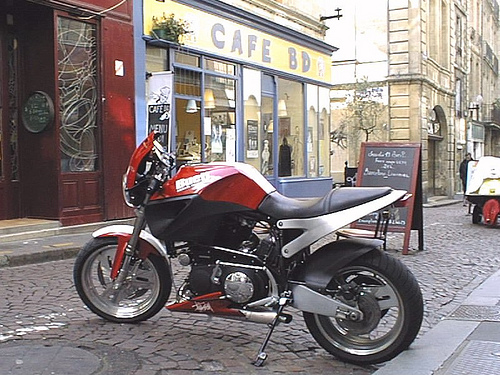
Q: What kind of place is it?
A: It is a road.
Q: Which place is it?
A: It is a road.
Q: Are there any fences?
A: No, there are no fences.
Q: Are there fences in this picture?
A: No, there are no fences.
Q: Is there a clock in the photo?
A: No, there are no clocks.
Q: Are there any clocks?
A: No, there are no clocks.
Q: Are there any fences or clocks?
A: No, there are no clocks or fences.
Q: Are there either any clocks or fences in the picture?
A: No, there are no clocks or fences.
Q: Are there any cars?
A: No, there are no cars.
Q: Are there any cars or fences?
A: No, there are no cars or fences.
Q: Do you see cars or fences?
A: No, there are no cars or fences.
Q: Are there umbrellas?
A: No, there are no umbrellas.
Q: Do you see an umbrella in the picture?
A: No, there are no umbrellas.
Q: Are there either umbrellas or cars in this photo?
A: No, there are no umbrellas or cars.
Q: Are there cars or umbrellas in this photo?
A: No, there are no umbrellas or cars.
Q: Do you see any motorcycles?
A: Yes, there is a motorcycle.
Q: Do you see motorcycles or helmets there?
A: Yes, there is a motorcycle.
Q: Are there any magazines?
A: No, there are no magazines.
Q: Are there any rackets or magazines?
A: No, there are no magazines or rackets.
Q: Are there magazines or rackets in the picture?
A: No, there are no magazines or rackets.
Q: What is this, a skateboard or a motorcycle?
A: This is a motorcycle.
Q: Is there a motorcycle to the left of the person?
A: Yes, there is a motorcycle to the left of the person.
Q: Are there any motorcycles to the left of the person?
A: Yes, there is a motorcycle to the left of the person.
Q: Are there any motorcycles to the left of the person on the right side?
A: Yes, there is a motorcycle to the left of the person.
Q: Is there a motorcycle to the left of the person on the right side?
A: Yes, there is a motorcycle to the left of the person.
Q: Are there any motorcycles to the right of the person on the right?
A: No, the motorcycle is to the left of the person.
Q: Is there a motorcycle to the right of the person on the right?
A: No, the motorcycle is to the left of the person.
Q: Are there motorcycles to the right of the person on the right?
A: No, the motorcycle is to the left of the person.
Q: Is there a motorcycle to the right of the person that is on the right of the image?
A: No, the motorcycle is to the left of the person.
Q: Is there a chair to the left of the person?
A: No, there is a motorcycle to the left of the person.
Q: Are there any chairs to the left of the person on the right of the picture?
A: No, there is a motorcycle to the left of the person.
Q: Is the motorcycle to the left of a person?
A: Yes, the motorcycle is to the left of a person.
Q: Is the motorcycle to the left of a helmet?
A: No, the motorcycle is to the left of a person.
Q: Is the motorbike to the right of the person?
A: No, the motorbike is to the left of the person.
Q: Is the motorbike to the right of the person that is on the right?
A: No, the motorbike is to the left of the person.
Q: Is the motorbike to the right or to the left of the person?
A: The motorbike is to the left of the person.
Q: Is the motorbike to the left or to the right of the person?
A: The motorbike is to the left of the person.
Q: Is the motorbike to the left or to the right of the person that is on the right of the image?
A: The motorbike is to the left of the person.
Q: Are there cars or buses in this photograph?
A: No, there are no cars or buses.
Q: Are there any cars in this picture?
A: No, there are no cars.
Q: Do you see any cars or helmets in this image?
A: No, there are no cars or helmets.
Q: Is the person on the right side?
A: Yes, the person is on the right of the image.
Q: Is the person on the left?
A: No, the person is on the right of the image.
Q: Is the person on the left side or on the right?
A: The person is on the right of the image.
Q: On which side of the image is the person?
A: The person is on the right of the image.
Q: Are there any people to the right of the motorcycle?
A: Yes, there is a person to the right of the motorcycle.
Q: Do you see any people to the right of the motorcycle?
A: Yes, there is a person to the right of the motorcycle.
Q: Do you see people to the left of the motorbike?
A: No, the person is to the right of the motorbike.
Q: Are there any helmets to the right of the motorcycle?
A: No, there is a person to the right of the motorcycle.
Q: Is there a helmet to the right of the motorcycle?
A: No, there is a person to the right of the motorcycle.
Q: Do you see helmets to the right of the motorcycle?
A: No, there is a person to the right of the motorcycle.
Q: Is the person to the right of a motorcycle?
A: Yes, the person is to the right of a motorcycle.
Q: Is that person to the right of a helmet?
A: No, the person is to the right of a motorcycle.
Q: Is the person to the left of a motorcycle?
A: No, the person is to the right of a motorcycle.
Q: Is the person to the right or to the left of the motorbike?
A: The person is to the right of the motorbike.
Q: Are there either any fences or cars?
A: No, there are no cars or fences.